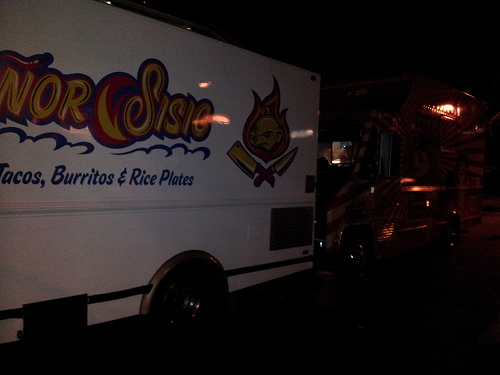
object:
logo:
[0, 51, 212, 148]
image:
[223, 142, 300, 188]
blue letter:
[0, 161, 195, 187]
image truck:
[311, 131, 499, 264]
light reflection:
[423, 100, 440, 117]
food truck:
[319, 86, 499, 268]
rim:
[180, 295, 210, 327]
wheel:
[147, 269, 230, 354]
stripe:
[0, 251, 320, 321]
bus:
[1, 0, 324, 352]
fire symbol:
[240, 80, 291, 161]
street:
[13, 247, 495, 372]